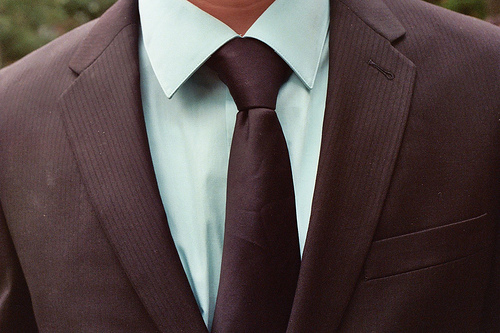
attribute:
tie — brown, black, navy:
[208, 39, 301, 332]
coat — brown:
[0, 0, 499, 331]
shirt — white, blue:
[135, 1, 331, 333]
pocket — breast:
[363, 209, 491, 333]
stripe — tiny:
[329, 44, 397, 314]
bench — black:
[61, 1, 101, 22]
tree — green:
[2, 14, 48, 54]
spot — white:
[40, 164, 61, 200]